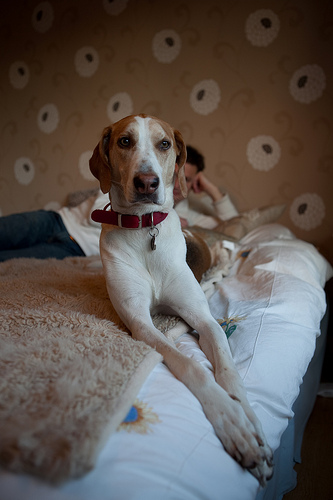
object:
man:
[0, 142, 241, 262]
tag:
[149, 229, 157, 254]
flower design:
[121, 398, 160, 437]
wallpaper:
[186, 15, 320, 187]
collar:
[91, 209, 168, 229]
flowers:
[7, 11, 327, 139]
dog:
[89, 112, 275, 488]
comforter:
[4, 220, 327, 464]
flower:
[112, 394, 160, 438]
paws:
[212, 395, 265, 471]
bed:
[2, 206, 332, 497]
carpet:
[285, 388, 332, 498]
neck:
[104, 204, 177, 227]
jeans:
[0, 206, 87, 262]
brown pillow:
[214, 200, 287, 241]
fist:
[192, 173, 202, 194]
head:
[173, 144, 205, 201]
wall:
[0, 0, 332, 246]